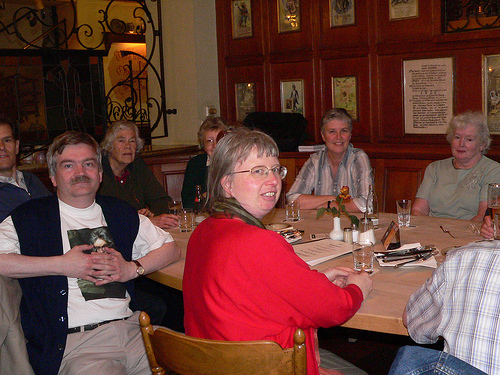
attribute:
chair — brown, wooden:
[137, 306, 321, 371]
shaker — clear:
[358, 205, 376, 251]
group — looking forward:
[0, 108, 499, 373]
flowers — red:
[328, 183, 353, 218]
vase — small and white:
[328, 216, 344, 241]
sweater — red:
[178, 212, 358, 373]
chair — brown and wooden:
[118, 302, 313, 374]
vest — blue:
[10, 193, 139, 373]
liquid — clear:
[395, 208, 413, 228]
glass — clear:
[395, 197, 412, 229]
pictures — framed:
[245, 7, 495, 134]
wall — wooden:
[213, 1, 498, 217]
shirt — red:
[181, 213, 363, 373]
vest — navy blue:
[5, 201, 163, 328]